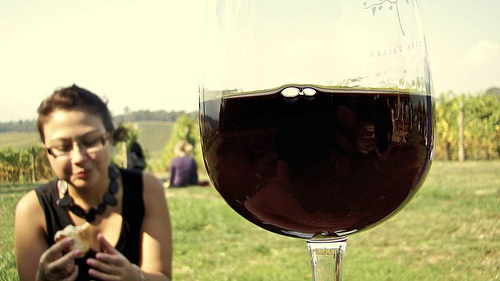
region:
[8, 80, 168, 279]
a woman holding a sandwhich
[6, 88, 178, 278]
a woman eating a sandwhich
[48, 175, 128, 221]
a woman's black chunky necklace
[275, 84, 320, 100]
a bubble in some wine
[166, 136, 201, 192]
a woman with blonde hair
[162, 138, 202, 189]
a woman sitting on the grass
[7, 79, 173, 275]
a woman wearing a black top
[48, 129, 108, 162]
a woman's glasses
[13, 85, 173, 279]
a woman wearing glasses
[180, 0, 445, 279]
a glass half full with wine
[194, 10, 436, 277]
glass of wine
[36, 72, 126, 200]
woman out of focus wearing glasses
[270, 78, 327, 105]
two small bubbles in top of liquid in glass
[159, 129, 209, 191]
person out of focus sitting on the grass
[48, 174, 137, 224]
black necklace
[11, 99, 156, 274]
woman holding a piece of bread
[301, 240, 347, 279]
glass stem of wine glass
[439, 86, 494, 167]
trees on the other side of the field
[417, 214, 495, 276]
green and yellow grass in a field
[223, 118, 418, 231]
reflection in the glass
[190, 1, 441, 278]
the glass is in the foreground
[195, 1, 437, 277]
the glass is transparent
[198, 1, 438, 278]
the glass is for wine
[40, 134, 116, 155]
the woman is wearing glasses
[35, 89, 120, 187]
the woman is looking down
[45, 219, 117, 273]
the woman is holding a sandwich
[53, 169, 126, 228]
the woman is wearing a collar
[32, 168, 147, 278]
the woman is wearing a tank top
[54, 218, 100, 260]
the sandwich is partically eaten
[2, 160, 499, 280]
the grass is green in color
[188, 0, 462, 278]
Wine glass in forefront.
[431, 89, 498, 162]
Corn growing in the background.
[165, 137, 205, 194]
Girl sitting on the grass.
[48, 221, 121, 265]
Sandwich in girl's hands.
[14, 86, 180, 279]
Girl eating a sandwich.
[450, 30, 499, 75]
White clouds in the sky.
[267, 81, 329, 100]
Bubbles in wine in glass.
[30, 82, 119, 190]
Brown glasses on girls face.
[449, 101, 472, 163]
Brown post in the ground.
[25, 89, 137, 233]
Back necklace on the girl.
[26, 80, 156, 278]
the woman eating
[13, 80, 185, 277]
the woman holding the bread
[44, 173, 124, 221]
the necklace around the neck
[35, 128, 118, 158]
the glasses of the woman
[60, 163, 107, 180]
the woman wearing red lipstick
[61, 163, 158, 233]
the necklace is black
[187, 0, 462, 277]
the glass of wine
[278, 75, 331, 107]
the bubbles in the wine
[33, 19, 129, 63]
the sun is shining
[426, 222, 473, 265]
the green trimmed grass